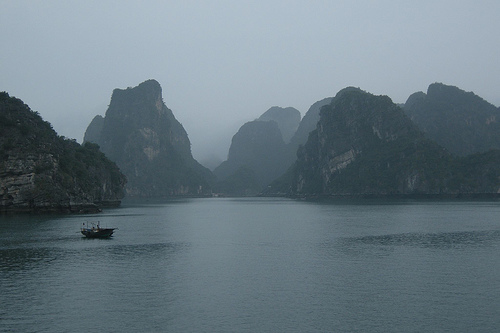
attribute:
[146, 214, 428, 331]
water — murky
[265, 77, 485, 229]
rock — large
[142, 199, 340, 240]
water — calm, black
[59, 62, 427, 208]
rock — large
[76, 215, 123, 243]
boat — sailing, alone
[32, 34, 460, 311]
scene — gray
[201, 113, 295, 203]
rock — large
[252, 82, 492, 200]
rock — large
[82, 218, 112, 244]
boat — small